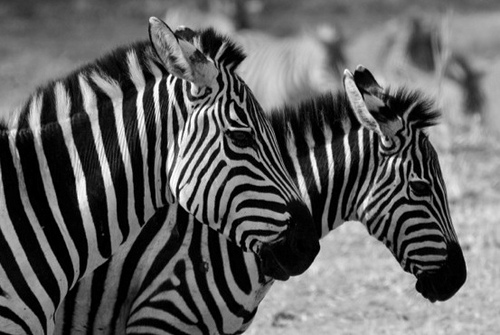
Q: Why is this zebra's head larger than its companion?
A: Older larger.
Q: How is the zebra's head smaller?
A: Younger animal.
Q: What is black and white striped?
A: Zebra.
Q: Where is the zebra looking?
A: To the right.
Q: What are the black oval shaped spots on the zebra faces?
A: Eyes.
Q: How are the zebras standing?
A: Next to each other.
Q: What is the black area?
A: Zebra noses.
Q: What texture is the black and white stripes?
A: Hairy.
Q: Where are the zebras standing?
A: Grass.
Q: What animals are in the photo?
A: Zebras.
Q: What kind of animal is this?
A: Zebra.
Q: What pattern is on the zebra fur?
A: Stripes.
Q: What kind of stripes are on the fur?
A: Black and white.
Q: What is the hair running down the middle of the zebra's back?
A: Mane.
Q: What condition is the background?
A: Blurred.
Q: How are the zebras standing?
A: Side by side.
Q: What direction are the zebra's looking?
A: Right.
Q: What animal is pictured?
A: Zebra.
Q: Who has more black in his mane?
A: The back zebra.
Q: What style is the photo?
A: Black and white.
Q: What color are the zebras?
A: Black and white.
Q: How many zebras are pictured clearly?
A: Two.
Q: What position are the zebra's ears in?
A: Tilted back.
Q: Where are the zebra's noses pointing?
A: To the right.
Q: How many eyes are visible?
A: Two.